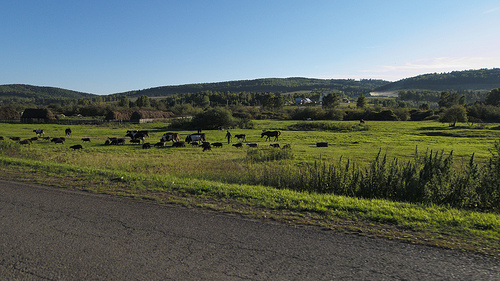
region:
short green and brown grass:
[163, 156, 224, 180]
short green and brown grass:
[375, 129, 409, 143]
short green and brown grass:
[424, 133, 491, 154]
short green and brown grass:
[346, 189, 408, 220]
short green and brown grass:
[442, 200, 495, 231]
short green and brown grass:
[124, 158, 175, 168]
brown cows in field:
[156, 130, 212, 153]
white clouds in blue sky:
[7, 5, 68, 36]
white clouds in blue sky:
[103, 3, 178, 46]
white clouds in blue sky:
[201, 30, 325, 69]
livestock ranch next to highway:
[2, 4, 492, 274]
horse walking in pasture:
[257, 125, 284, 145]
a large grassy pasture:
[1, 115, 496, 212]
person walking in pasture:
[223, 127, 234, 150]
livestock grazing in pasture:
[122, 123, 214, 150]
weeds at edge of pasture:
[201, 139, 498, 214]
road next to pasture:
[3, 176, 491, 273]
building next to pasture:
[19, 103, 53, 129]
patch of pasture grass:
[331, 128, 408, 149]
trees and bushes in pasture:
[164, 103, 255, 132]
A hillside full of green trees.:
[1, 62, 497, 133]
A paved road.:
[6, 170, 498, 276]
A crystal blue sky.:
[1, 0, 498, 97]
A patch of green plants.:
[183, 152, 498, 207]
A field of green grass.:
[3, 118, 498, 245]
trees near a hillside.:
[79, 77, 315, 127]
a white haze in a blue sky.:
[296, 43, 498, 83]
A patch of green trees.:
[270, 80, 470, 120]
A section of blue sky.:
[58, 8, 143, 45]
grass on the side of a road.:
[1, 153, 498, 233]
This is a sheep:
[67, 142, 84, 152]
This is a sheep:
[76, 133, 97, 144]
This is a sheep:
[61, 125, 80, 133]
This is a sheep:
[31, 124, 47, 137]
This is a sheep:
[52, 133, 65, 146]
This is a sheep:
[267, 138, 279, 150]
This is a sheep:
[279, 141, 298, 152]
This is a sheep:
[228, 140, 245, 152]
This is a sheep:
[241, 139, 260, 149]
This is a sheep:
[140, 138, 155, 153]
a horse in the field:
[258, 125, 282, 144]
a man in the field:
[223, 127, 234, 147]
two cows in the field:
[154, 129, 209, 146]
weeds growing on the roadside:
[208, 134, 497, 205]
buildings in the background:
[283, 87, 335, 110]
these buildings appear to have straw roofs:
[96, 104, 183, 126]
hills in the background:
[103, 65, 497, 98]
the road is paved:
[0, 167, 499, 279]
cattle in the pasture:
[4, 118, 153, 161]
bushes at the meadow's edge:
[163, 102, 258, 134]